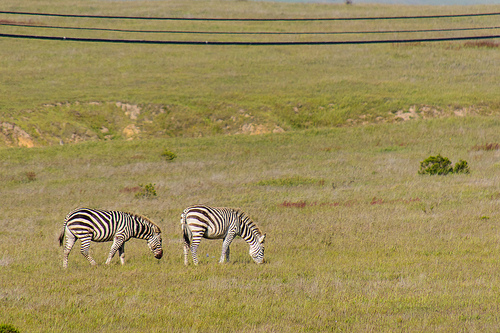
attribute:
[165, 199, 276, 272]
zebra — striped, grazing, peaceful, eating, black, standing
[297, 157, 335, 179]
grass — green, brown, dry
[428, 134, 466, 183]
bush — green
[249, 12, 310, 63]
line — black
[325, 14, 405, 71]
lines — black